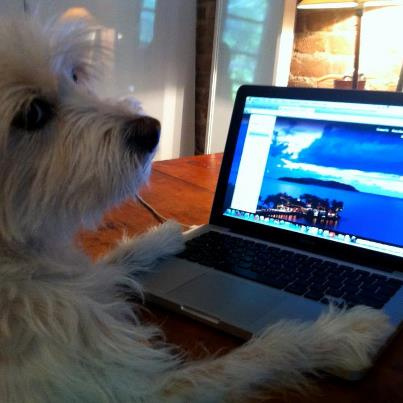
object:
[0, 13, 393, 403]
dog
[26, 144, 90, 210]
fur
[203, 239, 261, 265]
key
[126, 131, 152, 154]
nostril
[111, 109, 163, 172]
snout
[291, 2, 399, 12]
shade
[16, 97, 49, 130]
eye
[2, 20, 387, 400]
dog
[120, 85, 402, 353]
laptop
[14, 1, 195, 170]
wall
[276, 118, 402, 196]
clouds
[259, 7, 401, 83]
building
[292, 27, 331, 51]
brick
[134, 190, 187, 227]
black cord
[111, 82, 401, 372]
computer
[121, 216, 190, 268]
paw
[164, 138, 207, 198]
desk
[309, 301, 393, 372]
paw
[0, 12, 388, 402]
white dog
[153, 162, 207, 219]
table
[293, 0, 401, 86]
lamp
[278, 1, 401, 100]
wall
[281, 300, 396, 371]
white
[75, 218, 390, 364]
paws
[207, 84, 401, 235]
scene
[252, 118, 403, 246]
picture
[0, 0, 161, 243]
head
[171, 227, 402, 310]
keyboard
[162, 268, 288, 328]
mouse pad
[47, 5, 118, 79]
reflection